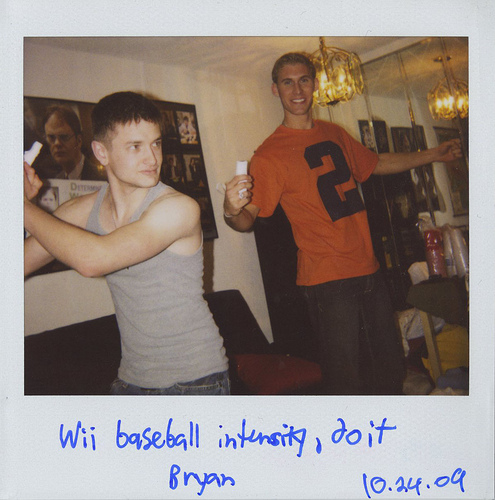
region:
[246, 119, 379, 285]
large black 2 on a red t-shirt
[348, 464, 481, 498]
handwritten date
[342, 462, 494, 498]
10.24.09 printed in blue handwriting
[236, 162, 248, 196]
white wii control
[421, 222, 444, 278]
stack of red cups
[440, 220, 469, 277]
stacks of plastic clear cups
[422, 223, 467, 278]
stacks of red and clear cups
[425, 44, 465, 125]
bright lights hanging from ceiling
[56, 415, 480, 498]
hand written words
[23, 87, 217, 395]
man preparing to swing white controller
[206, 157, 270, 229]
man is holding a wii controller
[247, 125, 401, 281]
man has a 2 on his shirt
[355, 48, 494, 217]
mirrors on the wall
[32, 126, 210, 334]
man is in the batter stand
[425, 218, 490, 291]
plastic cups on the table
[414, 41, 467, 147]
light reflection on the mirror wall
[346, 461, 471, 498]
the date of the picture was taken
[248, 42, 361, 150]
man is smiling at the camera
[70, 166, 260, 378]
man is wearing a grey tank top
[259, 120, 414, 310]
man's shirt is orange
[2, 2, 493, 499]
a Poloroid type image of two people in a room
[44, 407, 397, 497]
blue handwritten text on bottom of image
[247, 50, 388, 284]
man wearing an orange and black shirt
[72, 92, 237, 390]
man wearing a grey undershirt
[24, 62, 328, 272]
both men are holding game controllers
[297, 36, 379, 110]
a light hanging from above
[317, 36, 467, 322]
tall mirror on wall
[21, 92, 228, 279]
framed images on wall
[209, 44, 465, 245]
man holding his arms away from his body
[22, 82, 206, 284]
man holding his arms to the right of his body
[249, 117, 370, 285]
red tee shirt of man in the back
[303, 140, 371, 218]
black number two on red shirt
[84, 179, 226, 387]
gray undershirt on boy in front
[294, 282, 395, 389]
black pants of boy in back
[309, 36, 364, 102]
chandler hanging from the ceiling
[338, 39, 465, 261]
mirror covering back wall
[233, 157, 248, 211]
candle in man's right hand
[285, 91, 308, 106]
mouth of man in the red tee shirt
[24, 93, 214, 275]
black shelf on side wall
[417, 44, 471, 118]
Chandelier reflection in mirror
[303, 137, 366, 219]
number 2 on orange shirt is black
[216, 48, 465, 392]
man wearing orange shirt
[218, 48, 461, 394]
man holding white remote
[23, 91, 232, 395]
man in gray wife beater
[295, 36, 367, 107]
Chandelier near mirrors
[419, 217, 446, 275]
Red cups on table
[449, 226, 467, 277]
White cups next to red cups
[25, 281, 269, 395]
Sofa behind both men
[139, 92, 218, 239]
Picture frame behind men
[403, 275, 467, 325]
Green tablecloth on table